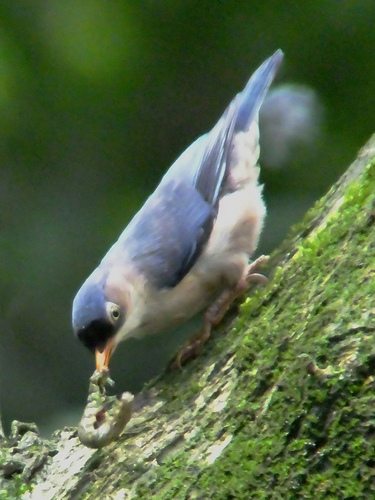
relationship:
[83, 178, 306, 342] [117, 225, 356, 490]
bird sitting in branch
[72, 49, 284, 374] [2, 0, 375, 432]
bird holding green background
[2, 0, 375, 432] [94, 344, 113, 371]
green background in mouth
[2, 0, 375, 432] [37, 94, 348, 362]
green background caught by bird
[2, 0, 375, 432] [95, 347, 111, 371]
green background in beak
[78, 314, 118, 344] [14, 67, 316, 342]
spot on bird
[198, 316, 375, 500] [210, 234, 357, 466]
grass on trunk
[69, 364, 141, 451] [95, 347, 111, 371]
caterpillar in beak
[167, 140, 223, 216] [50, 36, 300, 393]
feathers on bird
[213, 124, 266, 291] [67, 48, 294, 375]
white underside underside bird.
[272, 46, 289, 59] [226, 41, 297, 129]
edge of tail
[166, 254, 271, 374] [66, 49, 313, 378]
branch for bird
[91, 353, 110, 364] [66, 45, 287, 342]
beak of bird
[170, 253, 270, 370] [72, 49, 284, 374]
foot of bird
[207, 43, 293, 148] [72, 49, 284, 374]
tail feathers of bird